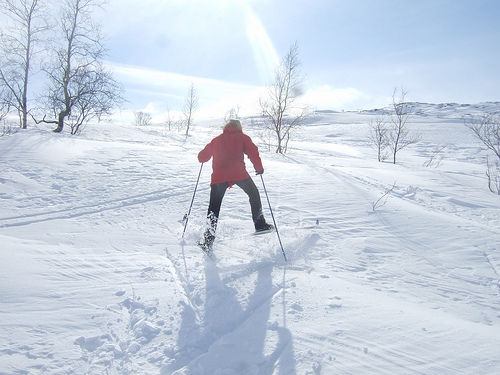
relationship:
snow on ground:
[5, 106, 493, 363] [3, 107, 492, 373]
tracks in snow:
[162, 240, 286, 372] [5, 106, 493, 363]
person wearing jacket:
[188, 120, 274, 249] [194, 126, 259, 181]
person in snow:
[188, 120, 274, 249] [5, 106, 493, 363]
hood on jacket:
[219, 120, 248, 135] [197, 125, 265, 185]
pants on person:
[200, 180, 266, 240] [188, 120, 274, 249]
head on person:
[222, 115, 243, 133] [188, 120, 274, 249]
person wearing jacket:
[188, 120, 274, 249] [197, 125, 265, 185]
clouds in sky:
[2, 0, 499, 126] [0, 100, 500, 370]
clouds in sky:
[2, 0, 499, 126] [134, 8, 402, 75]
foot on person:
[194, 234, 213, 247] [188, 120, 274, 249]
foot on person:
[251, 216, 281, 232] [188, 120, 274, 249]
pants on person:
[203, 175, 267, 242] [188, 120, 274, 249]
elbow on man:
[197, 147, 207, 164] [197, 115, 270, 246]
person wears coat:
[188, 120, 274, 249] [197, 128, 262, 183]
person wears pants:
[188, 120, 274, 249] [204, 176, 266, 233]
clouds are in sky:
[2, 0, 499, 126] [134, 8, 402, 75]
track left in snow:
[0, 184, 209, 227] [5, 106, 493, 363]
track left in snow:
[0, 195, 168, 229] [5, 106, 493, 363]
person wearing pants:
[188, 120, 274, 249] [203, 175, 267, 242]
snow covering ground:
[5, 106, 493, 363] [3, 107, 492, 373]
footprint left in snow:
[121, 167, 141, 175] [5, 106, 493, 363]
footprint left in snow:
[50, 181, 66, 190] [5, 106, 493, 363]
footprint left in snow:
[67, 161, 84, 167] [5, 106, 493, 363]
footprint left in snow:
[93, 160, 111, 168] [5, 106, 493, 363]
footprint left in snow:
[125, 156, 147, 163] [5, 106, 493, 363]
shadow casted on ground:
[155, 230, 322, 372] [3, 107, 492, 373]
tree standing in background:
[32, 0, 130, 133] [1, 1, 479, 151]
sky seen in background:
[134, 8, 402, 75] [1, 1, 479, 151]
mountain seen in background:
[357, 99, 483, 122] [1, 1, 479, 151]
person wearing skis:
[172, 121, 293, 251] [186, 213, 306, 258]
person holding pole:
[188, 120, 274, 249] [179, 156, 286, 256]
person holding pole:
[188, 120, 274, 249] [181, 162, 296, 262]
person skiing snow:
[188, 120, 274, 249] [18, 250, 481, 360]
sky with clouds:
[134, 8, 402, 75] [340, 15, 440, 77]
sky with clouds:
[134, 8, 402, 75] [164, 1, 283, 40]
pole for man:
[181, 155, 201, 235] [197, 115, 270, 246]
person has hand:
[188, 120, 274, 249] [193, 147, 209, 167]